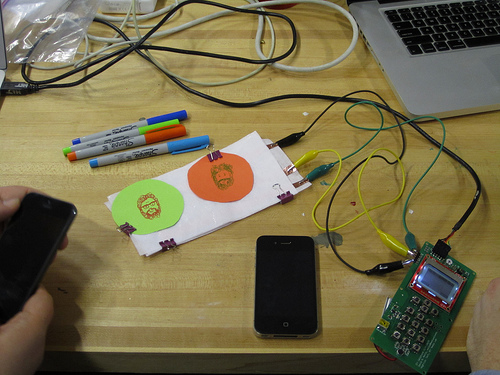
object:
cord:
[272, 90, 447, 277]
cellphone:
[253, 234, 319, 339]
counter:
[0, 0, 499, 354]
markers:
[62, 118, 180, 156]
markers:
[67, 124, 188, 162]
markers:
[88, 134, 209, 171]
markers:
[71, 109, 188, 145]